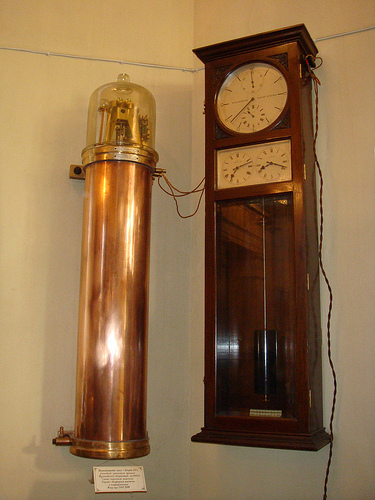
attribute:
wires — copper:
[157, 172, 204, 218]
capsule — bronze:
[64, 70, 175, 473]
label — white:
[86, 459, 150, 496]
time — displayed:
[213, 73, 307, 143]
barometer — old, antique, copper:
[52, 69, 180, 463]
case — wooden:
[188, 20, 332, 451]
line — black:
[224, 105, 247, 118]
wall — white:
[0, 2, 371, 489]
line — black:
[262, 67, 270, 78]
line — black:
[249, 69, 253, 88]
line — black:
[229, 72, 242, 83]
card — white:
[80, 461, 163, 498]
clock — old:
[191, 25, 316, 434]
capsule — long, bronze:
[68, 71, 156, 460]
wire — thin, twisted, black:
[307, 58, 334, 331]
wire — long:
[302, 46, 364, 491]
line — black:
[275, 90, 287, 96]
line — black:
[235, 116, 243, 130]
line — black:
[220, 84, 231, 94]